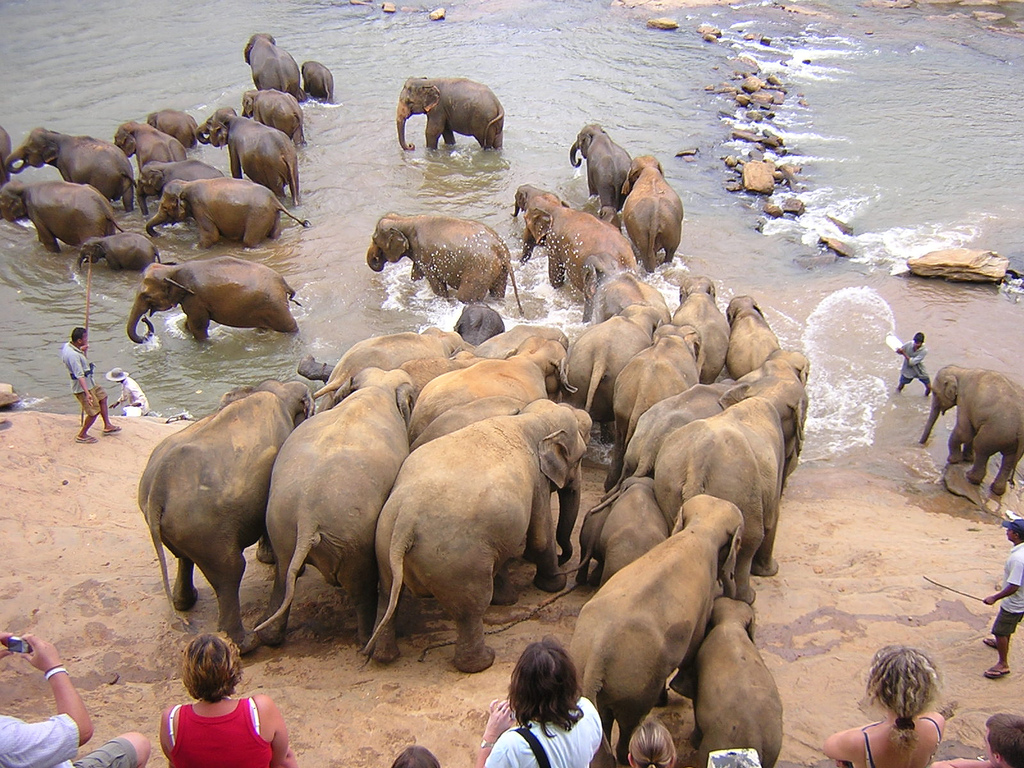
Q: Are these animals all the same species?
A: Yes, all the animals are elephants.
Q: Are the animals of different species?
A: No, all the animals are elephants.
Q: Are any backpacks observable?
A: No, there are no backpacks.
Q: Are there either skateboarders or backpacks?
A: No, there are no backpacks or skateboarders.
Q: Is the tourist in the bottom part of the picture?
A: Yes, the tourist is in the bottom of the image.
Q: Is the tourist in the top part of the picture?
A: No, the tourist is in the bottom of the image.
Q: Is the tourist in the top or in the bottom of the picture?
A: The tourist is in the bottom of the image.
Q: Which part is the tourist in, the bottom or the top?
A: The tourist is in the bottom of the image.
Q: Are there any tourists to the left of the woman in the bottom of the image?
A: Yes, there is a tourist to the left of the woman.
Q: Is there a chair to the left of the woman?
A: No, there is a tourist to the left of the woman.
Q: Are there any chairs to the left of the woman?
A: No, there is a tourist to the left of the woman.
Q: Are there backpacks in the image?
A: No, there are no backpacks.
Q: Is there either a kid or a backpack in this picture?
A: No, there are no backpacks or children.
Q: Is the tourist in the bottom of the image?
A: Yes, the tourist is in the bottom of the image.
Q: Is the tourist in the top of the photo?
A: No, the tourist is in the bottom of the image.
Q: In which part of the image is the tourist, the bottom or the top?
A: The tourist is in the bottom of the image.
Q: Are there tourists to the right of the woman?
A: Yes, there is a tourist to the right of the woman.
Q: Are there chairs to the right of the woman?
A: No, there is a tourist to the right of the woman.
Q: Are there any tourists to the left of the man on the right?
A: Yes, there is a tourist to the left of the man.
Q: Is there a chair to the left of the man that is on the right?
A: No, there is a tourist to the left of the man.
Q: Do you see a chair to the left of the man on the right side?
A: No, there is a tourist to the left of the man.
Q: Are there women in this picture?
A: Yes, there is a woman.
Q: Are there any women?
A: Yes, there is a woman.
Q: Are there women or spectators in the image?
A: Yes, there is a woman.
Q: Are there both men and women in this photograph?
A: Yes, there are both a woman and a man.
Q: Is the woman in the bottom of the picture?
A: Yes, the woman is in the bottom of the image.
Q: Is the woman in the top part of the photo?
A: No, the woman is in the bottom of the image.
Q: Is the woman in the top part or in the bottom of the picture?
A: The woman is in the bottom of the image.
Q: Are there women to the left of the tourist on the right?
A: Yes, there is a woman to the left of the tourist.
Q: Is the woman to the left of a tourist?
A: Yes, the woman is to the left of a tourist.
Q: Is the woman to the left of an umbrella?
A: No, the woman is to the left of a tourist.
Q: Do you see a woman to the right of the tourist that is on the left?
A: Yes, there is a woman to the right of the tourist.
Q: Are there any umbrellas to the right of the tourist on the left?
A: No, there is a woman to the right of the tourist.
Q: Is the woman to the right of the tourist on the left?
A: Yes, the woman is to the right of the tourist.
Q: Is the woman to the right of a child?
A: No, the woman is to the right of the tourist.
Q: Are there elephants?
A: Yes, there is an elephant.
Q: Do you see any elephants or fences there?
A: Yes, there is an elephant.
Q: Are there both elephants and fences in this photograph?
A: No, there is an elephant but no fences.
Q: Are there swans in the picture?
A: No, there are no swans.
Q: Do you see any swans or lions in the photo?
A: No, there are no swans or lions.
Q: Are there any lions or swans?
A: No, there are no swans or lions.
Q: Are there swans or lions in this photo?
A: No, there are no swans or lions.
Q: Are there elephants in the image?
A: Yes, there are elephants.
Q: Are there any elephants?
A: Yes, there are elephants.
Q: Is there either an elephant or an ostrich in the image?
A: Yes, there are elephants.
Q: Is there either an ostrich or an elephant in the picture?
A: Yes, there are elephants.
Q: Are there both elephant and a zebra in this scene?
A: No, there are elephants but no zebras.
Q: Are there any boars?
A: No, there are no boars.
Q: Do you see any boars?
A: No, there are no boars.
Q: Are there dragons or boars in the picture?
A: No, there are no boars or dragons.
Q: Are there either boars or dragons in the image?
A: No, there are no boars or dragons.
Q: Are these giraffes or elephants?
A: These are elephants.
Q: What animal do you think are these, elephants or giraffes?
A: These are elephants.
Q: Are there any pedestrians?
A: No, there are no pedestrians.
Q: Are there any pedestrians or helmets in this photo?
A: No, there are no pedestrians or helmets.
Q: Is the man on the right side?
A: Yes, the man is on the right of the image.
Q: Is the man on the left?
A: No, the man is on the right of the image.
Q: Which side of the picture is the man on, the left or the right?
A: The man is on the right of the image.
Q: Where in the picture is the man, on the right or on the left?
A: The man is on the right of the image.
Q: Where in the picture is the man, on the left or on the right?
A: The man is on the right of the image.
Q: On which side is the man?
A: The man is on the right of the image.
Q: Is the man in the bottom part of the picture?
A: Yes, the man is in the bottom of the image.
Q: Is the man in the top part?
A: No, the man is in the bottom of the image.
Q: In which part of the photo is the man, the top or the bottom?
A: The man is in the bottom of the image.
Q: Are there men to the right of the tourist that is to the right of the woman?
A: Yes, there is a man to the right of the tourist.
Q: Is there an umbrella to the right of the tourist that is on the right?
A: No, there is a man to the right of the tourist.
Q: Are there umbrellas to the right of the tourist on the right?
A: No, there is a man to the right of the tourist.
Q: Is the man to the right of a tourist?
A: Yes, the man is to the right of a tourist.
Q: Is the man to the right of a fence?
A: No, the man is to the right of a tourist.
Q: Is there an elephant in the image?
A: Yes, there is an elephant.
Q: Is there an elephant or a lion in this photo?
A: Yes, there is an elephant.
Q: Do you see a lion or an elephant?
A: Yes, there is an elephant.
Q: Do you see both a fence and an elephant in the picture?
A: No, there is an elephant but no fences.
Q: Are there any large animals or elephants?
A: Yes, there is a large elephant.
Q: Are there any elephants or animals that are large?
A: Yes, the elephant is large.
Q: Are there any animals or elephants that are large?
A: Yes, the elephant is large.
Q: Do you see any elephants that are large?
A: Yes, there is a large elephant.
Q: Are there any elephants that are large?
A: Yes, there is an elephant that is large.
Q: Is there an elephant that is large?
A: Yes, there is an elephant that is large.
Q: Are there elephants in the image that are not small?
A: Yes, there is a large elephant.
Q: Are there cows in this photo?
A: No, there are no cows.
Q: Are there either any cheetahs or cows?
A: No, there are no cows or cheetahs.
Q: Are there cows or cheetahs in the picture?
A: No, there are no cows or cheetahs.